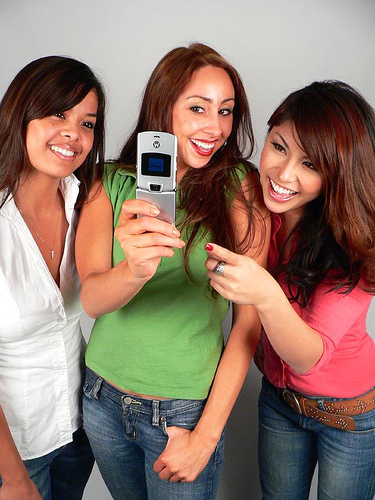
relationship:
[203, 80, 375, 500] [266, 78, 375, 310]
female with darl hair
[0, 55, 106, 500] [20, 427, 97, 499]
female wearing blue jeans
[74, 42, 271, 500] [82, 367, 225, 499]
female wearing blue jeans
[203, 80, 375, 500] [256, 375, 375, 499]
female wearing blue jeans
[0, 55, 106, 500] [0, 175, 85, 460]
female wearing blouse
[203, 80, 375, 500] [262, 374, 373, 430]
female wearing belt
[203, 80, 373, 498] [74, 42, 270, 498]
female standing with female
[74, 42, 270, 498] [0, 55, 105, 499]
female standing with female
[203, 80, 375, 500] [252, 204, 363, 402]
female wearing shirt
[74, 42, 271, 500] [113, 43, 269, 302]
female has hair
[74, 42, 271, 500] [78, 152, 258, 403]
female wearing t-shirt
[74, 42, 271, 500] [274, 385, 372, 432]
female wearing belt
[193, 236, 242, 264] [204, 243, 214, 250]
finger with polish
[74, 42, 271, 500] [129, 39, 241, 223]
female holding phone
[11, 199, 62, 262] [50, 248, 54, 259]
necklace has charm